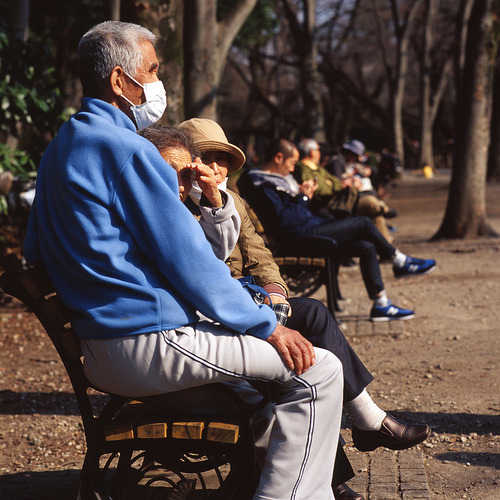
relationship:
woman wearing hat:
[143, 120, 251, 263] [176, 110, 247, 167]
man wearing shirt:
[24, 19, 350, 498] [32, 95, 272, 336]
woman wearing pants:
[143, 120, 251, 263] [274, 288, 374, 404]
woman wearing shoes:
[183, 102, 431, 496] [338, 410, 432, 495]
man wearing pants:
[31, 19, 433, 496] [82, 325, 346, 498]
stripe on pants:
[157, 327, 318, 500] [82, 325, 346, 498]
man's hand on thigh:
[264, 325, 318, 372] [179, 329, 319, 388]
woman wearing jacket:
[183, 102, 431, 496] [225, 191, 285, 296]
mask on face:
[113, 71, 170, 130] [134, 40, 162, 115]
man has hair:
[24, 19, 350, 498] [78, 17, 159, 101]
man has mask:
[24, 19, 350, 498] [113, 71, 169, 129]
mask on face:
[113, 71, 169, 129] [134, 40, 158, 115]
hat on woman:
[175, 117, 246, 171] [183, 102, 431, 496]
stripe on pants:
[157, 327, 236, 378] [82, 325, 348, 498]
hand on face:
[183, 147, 219, 194] [160, 143, 197, 200]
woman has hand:
[143, 120, 251, 263] [183, 147, 219, 194]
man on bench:
[24, 19, 350, 498] [76, 390, 249, 470]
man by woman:
[24, 19, 350, 498] [143, 120, 244, 254]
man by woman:
[24, 19, 350, 498] [183, 102, 431, 496]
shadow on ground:
[392, 407, 494, 462] [357, 313, 497, 498]